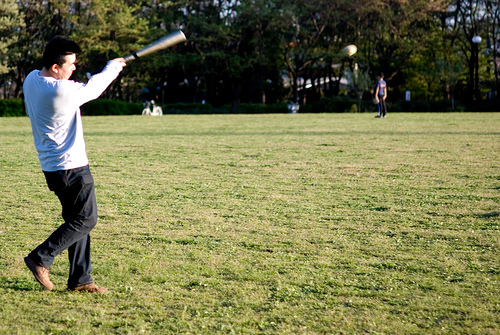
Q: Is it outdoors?
A: Yes, it is outdoors.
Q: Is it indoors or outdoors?
A: It is outdoors.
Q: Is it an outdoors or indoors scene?
A: It is outdoors.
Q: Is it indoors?
A: No, it is outdoors.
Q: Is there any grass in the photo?
A: Yes, there is grass.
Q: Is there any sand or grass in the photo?
A: Yes, there is grass.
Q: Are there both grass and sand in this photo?
A: No, there is grass but no sand.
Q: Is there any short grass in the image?
A: Yes, there is short grass.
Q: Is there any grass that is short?
A: Yes, there is grass that is short.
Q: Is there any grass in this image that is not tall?
A: Yes, there is short grass.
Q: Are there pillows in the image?
A: No, there are no pillows.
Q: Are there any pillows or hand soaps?
A: No, there are no pillows or hand soaps.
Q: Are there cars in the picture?
A: No, there are no cars.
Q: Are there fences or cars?
A: No, there are no cars or fences.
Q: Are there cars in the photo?
A: No, there are no cars.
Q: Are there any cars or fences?
A: No, there are no cars or fences.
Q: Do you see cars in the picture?
A: No, there are no cars.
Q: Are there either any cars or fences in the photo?
A: No, there are no cars or fences.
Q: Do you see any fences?
A: No, there are no fences.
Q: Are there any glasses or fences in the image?
A: No, there are no fences or glasses.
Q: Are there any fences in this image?
A: No, there are no fences.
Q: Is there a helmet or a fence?
A: No, there are no fences or helmets.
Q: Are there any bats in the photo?
A: Yes, there is a bat.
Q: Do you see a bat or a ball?
A: Yes, there is a bat.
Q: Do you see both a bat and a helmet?
A: No, there is a bat but no helmets.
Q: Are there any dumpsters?
A: No, there are no dumpsters.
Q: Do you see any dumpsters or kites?
A: No, there are no dumpsters or kites.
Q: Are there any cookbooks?
A: No, there are no cookbooks.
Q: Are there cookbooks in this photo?
A: No, there are no cookbooks.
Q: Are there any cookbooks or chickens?
A: No, there are no cookbooks or chickens.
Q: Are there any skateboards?
A: No, there are no skateboards.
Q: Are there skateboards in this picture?
A: No, there are no skateboards.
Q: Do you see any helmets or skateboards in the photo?
A: No, there are no skateboards or helmets.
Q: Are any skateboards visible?
A: No, there are no skateboards.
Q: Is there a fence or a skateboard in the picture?
A: No, there are no skateboards or fences.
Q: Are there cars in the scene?
A: No, there are no cars.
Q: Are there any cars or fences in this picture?
A: No, there are no cars or fences.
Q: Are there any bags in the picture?
A: No, there are no bags.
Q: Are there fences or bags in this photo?
A: No, there are no bags or fences.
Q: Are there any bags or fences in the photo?
A: No, there are no bags or fences.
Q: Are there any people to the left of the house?
A: No, the person is to the right of the house.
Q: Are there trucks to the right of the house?
A: No, there is a person to the right of the house.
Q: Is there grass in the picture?
A: Yes, there is grass.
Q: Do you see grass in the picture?
A: Yes, there is grass.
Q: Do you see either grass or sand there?
A: Yes, there is grass.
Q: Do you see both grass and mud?
A: No, there is grass but no mud.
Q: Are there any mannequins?
A: No, there are no mannequins.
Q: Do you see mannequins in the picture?
A: No, there are no mannequins.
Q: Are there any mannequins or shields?
A: No, there are no mannequins or shields.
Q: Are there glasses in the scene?
A: No, there are no glasses.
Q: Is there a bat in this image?
A: Yes, there is a bat.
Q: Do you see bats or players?
A: Yes, there is a bat.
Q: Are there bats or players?
A: Yes, there is a bat.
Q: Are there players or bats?
A: Yes, there is a bat.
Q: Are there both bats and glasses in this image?
A: No, there is a bat but no glasses.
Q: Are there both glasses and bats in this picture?
A: No, there is a bat but no glasses.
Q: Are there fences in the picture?
A: No, there are no fences.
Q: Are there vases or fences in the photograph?
A: No, there are no fences or vases.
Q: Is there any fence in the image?
A: No, there are no fences.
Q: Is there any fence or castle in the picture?
A: No, there are no fences or castles.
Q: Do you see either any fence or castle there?
A: No, there are no fences or castles.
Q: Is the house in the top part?
A: Yes, the house is in the top of the image.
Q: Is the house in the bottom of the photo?
A: No, the house is in the top of the image.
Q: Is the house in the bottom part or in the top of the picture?
A: The house is in the top of the image.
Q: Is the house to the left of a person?
A: Yes, the house is to the left of a person.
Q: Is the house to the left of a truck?
A: No, the house is to the left of a person.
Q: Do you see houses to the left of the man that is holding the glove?
A: Yes, there is a house to the left of the man.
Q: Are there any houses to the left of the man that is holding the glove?
A: Yes, there is a house to the left of the man.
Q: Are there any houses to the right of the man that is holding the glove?
A: No, the house is to the left of the man.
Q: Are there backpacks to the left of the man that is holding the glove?
A: No, there is a house to the left of the man.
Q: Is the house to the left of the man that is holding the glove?
A: Yes, the house is to the left of the man.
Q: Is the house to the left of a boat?
A: No, the house is to the left of the man.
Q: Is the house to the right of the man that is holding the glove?
A: No, the house is to the left of the man.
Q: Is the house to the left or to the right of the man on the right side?
A: The house is to the left of the man.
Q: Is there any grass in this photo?
A: Yes, there is grass.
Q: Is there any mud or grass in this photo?
A: Yes, there is grass.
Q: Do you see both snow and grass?
A: No, there is grass but no snow.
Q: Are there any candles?
A: No, there are no candles.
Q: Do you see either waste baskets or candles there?
A: No, there are no candles or waste baskets.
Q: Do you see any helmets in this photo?
A: No, there are no helmets.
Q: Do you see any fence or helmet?
A: No, there are no helmets or fences.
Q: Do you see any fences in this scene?
A: No, there are no fences.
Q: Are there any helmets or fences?
A: No, there are no fences or helmets.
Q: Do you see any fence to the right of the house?
A: No, there is a man to the right of the house.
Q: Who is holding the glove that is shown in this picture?
A: The man is holding the glove.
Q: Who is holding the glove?
A: The man is holding the glove.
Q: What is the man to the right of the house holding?
A: The man is holding the glove.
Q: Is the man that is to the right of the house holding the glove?
A: Yes, the man is holding the glove.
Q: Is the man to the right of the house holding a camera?
A: No, the man is holding the glove.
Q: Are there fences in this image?
A: No, there are no fences.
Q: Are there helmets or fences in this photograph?
A: No, there are no fences or helmets.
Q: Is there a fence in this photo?
A: No, there are no fences.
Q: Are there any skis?
A: No, there are no skis.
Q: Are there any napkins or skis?
A: No, there are no skis or napkins.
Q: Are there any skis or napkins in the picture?
A: No, there are no skis or napkins.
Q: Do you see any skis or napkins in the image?
A: No, there are no skis or napkins.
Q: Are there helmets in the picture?
A: No, there are no helmets.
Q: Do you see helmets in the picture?
A: No, there are no helmets.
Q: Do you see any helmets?
A: No, there are no helmets.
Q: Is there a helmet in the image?
A: No, there are no helmets.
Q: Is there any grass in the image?
A: Yes, there is grass.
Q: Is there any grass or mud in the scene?
A: Yes, there is grass.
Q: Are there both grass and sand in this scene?
A: No, there is grass but no sand.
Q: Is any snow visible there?
A: No, there is no snow.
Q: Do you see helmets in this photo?
A: No, there are no helmets.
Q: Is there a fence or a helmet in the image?
A: No, there are no helmets or fences.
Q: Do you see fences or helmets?
A: No, there are no helmets or fences.